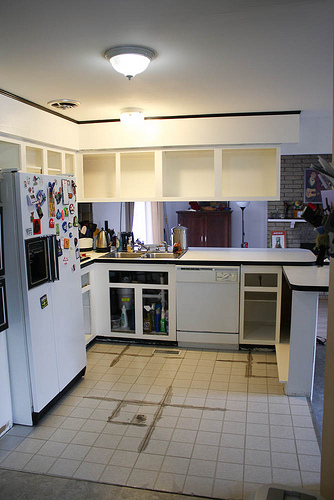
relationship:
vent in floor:
[151, 345, 184, 356] [4, 337, 326, 493]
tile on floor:
[142, 358, 165, 371] [4, 337, 326, 493]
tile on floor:
[188, 377, 211, 389] [4, 337, 326, 493]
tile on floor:
[168, 426, 199, 444] [4, 337, 326, 493]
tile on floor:
[88, 407, 117, 420] [4, 337, 326, 493]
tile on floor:
[97, 370, 122, 381] [4, 337, 326, 493]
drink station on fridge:
[26, 236, 60, 289] [1, 167, 85, 425]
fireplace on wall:
[295, 238, 331, 282] [272, 150, 328, 252]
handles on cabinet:
[133, 284, 142, 297] [96, 262, 176, 346]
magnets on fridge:
[30, 186, 79, 238] [9, 167, 102, 397]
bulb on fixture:
[109, 53, 149, 76] [101, 44, 158, 81]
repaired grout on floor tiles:
[96, 339, 184, 363] [4, 343, 309, 496]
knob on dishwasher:
[221, 270, 232, 282] [171, 261, 241, 354]